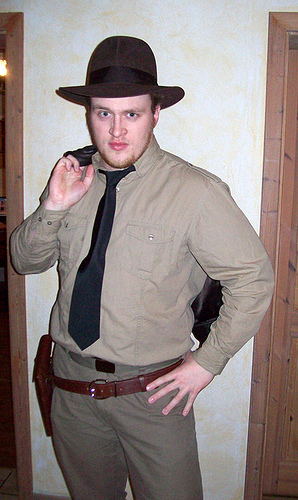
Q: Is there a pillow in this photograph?
A: No, there are no pillows.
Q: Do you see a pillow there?
A: No, there are no pillows.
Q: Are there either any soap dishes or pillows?
A: No, there are no pillows or soap dishes.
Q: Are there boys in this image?
A: No, there are no boys.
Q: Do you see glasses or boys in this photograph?
A: No, there are no boys or glasses.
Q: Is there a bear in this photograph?
A: No, there are no bears.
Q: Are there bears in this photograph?
A: No, there are no bears.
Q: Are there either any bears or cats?
A: No, there are no bears or cats.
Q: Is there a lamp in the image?
A: No, there are no lamps.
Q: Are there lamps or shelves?
A: No, there are no lamps or shelves.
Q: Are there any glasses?
A: No, there are no glasses.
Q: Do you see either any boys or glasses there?
A: No, there are no glasses or boys.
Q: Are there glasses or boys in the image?
A: No, there are no glasses or boys.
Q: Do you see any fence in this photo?
A: No, there are no fences.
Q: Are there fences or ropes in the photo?
A: No, there are no fences or ropes.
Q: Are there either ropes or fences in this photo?
A: No, there are no fences or ropes.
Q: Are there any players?
A: No, there are no players.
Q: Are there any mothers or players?
A: No, there are no players or mothers.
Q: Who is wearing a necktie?
A: The man is wearing a necktie.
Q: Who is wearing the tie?
A: The man is wearing a necktie.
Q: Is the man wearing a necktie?
A: Yes, the man is wearing a necktie.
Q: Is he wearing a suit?
A: No, the man is wearing a necktie.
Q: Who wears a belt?
A: The man wears a belt.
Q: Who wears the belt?
A: The man wears a belt.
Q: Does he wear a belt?
A: Yes, the man wears a belt.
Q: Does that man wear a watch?
A: No, the man wears a belt.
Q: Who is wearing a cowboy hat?
A: The man is wearing a cowboy hat.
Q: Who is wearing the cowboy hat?
A: The man is wearing a cowboy hat.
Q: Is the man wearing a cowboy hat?
A: Yes, the man is wearing a cowboy hat.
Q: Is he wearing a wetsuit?
A: No, the man is wearing a cowboy hat.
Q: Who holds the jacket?
A: The man holds the jacket.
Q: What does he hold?
A: The man holds the jacket.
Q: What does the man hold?
A: The man holds the jacket.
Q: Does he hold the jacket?
A: Yes, the man holds the jacket.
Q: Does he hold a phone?
A: No, the man holds the jacket.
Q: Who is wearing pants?
A: The man is wearing pants.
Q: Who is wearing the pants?
A: The man is wearing pants.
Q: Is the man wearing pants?
A: Yes, the man is wearing pants.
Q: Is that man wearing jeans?
A: No, the man is wearing pants.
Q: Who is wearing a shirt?
A: The man is wearing a shirt.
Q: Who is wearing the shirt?
A: The man is wearing a shirt.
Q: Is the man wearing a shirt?
A: Yes, the man is wearing a shirt.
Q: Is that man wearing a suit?
A: No, the man is wearing a shirt.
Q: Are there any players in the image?
A: No, there are no players.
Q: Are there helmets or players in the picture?
A: No, there are no players or helmets.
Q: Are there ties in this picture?
A: Yes, there is a tie.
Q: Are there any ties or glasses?
A: Yes, there is a tie.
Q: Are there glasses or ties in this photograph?
A: Yes, there is a tie.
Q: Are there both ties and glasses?
A: No, there is a tie but no glasses.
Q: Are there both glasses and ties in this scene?
A: No, there is a tie but no glasses.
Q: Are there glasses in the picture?
A: No, there are no glasses.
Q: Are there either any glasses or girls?
A: No, there are no glasses or girls.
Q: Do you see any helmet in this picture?
A: No, there are no helmets.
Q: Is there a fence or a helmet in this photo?
A: No, there are no helmets or fences.